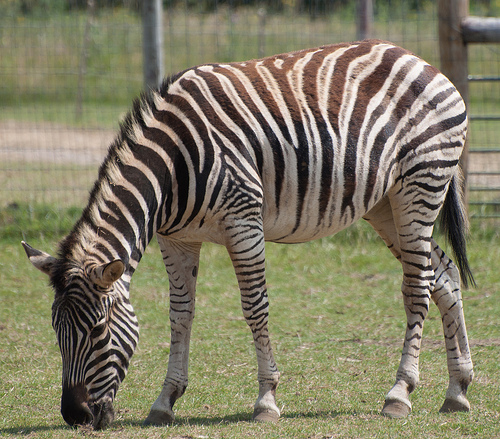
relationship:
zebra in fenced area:
[18, 43, 469, 428] [0, 3, 53, 436]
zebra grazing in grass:
[18, 43, 469, 428] [2, 195, 499, 434]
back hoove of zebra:
[377, 375, 421, 422] [18, 43, 469, 428]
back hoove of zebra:
[437, 370, 477, 415] [18, 43, 469, 428]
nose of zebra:
[58, 399, 92, 428] [18, 43, 469, 428]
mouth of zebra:
[89, 395, 109, 431] [18, 43, 469, 428]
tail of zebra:
[443, 165, 475, 289] [18, 43, 469, 428]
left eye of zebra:
[86, 316, 108, 340] [18, 43, 469, 428]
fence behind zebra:
[5, 0, 497, 235] [18, 43, 469, 428]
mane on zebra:
[66, 113, 158, 252] [18, 43, 469, 428]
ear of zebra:
[19, 236, 59, 281] [18, 43, 469, 428]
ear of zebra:
[88, 256, 126, 288] [18, 43, 469, 428]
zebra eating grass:
[18, 43, 469, 428] [2, 195, 499, 434]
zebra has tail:
[18, 43, 469, 428] [442, 164, 494, 284]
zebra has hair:
[18, 43, 469, 428] [50, 46, 180, 275]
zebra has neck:
[18, 43, 469, 428] [79, 134, 167, 269]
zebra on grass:
[18, 43, 469, 428] [0, 0, 498, 437]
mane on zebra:
[54, 73, 178, 261] [18, 43, 469, 428]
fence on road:
[5, 0, 497, 235] [0, 107, 497, 202]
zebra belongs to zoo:
[18, 43, 469, 428] [4, 3, 496, 437]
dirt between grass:
[334, 330, 362, 347] [310, 343, 333, 369]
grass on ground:
[310, 343, 333, 369] [5, 209, 498, 435]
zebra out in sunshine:
[18, 43, 469, 428] [36, 138, 484, 427]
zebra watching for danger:
[18, 43, 469, 428] [52, 375, 171, 417]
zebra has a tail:
[18, 43, 469, 428] [448, 174, 482, 324]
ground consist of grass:
[1, 325, 498, 439] [33, 381, 302, 439]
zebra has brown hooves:
[21, 37, 478, 432] [32, 134, 245, 431]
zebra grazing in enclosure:
[18, 43, 469, 428] [98, 188, 429, 358]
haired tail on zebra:
[454, 230, 472, 296] [21, 37, 478, 432]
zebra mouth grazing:
[21, 37, 478, 432] [62, 341, 159, 439]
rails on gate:
[16, 211, 34, 253] [12, 150, 498, 303]